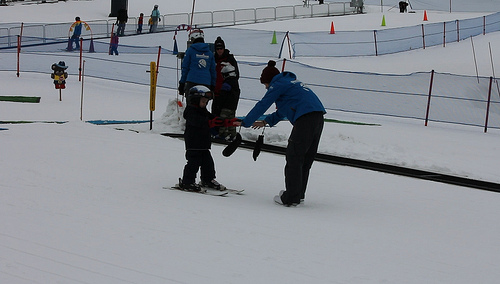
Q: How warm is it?
A: Its cold.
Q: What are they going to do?
A: Ski.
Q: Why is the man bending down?
A: Helping the boy.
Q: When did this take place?
A: Winter.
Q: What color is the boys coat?
A: Blue.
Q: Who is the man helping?
A: A young boy.